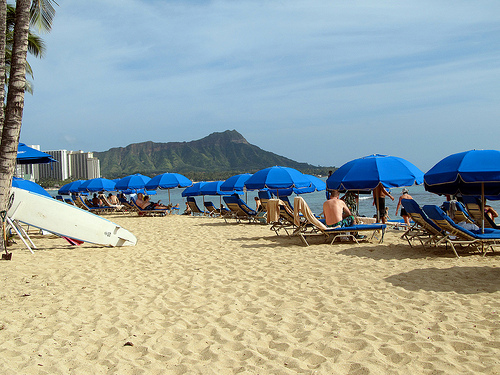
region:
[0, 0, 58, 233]
brown and green palm trees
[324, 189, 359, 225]
man in green swimming trunks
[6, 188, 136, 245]
white and blue surfboard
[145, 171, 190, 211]
large bright blue beach umbrella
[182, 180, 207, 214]
large bright blue beach umbrella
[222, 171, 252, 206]
large bright blue beach umbrella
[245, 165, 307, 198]
large bright blue beach umbrella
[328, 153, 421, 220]
large bright blue beach umbrella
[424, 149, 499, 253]
large bright blue beach umbrella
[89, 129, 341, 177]
green and brown mountain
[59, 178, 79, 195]
the large blue umbrella on the beach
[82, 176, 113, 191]
the large blue umbrella on the beach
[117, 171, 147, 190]
the large blue umbrella on the beach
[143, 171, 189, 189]
the large blue umbrella on the beach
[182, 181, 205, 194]
the large blue umbrella on the beach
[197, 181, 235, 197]
the large blue umbrella on the beach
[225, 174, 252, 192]
the large blue umbrella on the beach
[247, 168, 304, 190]
the large blue umbrella on the beach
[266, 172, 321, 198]
the large blue umbrella on the beach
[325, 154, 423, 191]
the large blue umbrella on the beach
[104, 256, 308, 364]
sand on a beach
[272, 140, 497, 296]
large open blue umbrellas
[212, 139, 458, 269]
blue umbrellas that are large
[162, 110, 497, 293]
blue umbrellas that are open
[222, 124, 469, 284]
blue umbrellas that are outside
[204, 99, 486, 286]
blue umbrellas in the sand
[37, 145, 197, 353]
a surfboard on the sand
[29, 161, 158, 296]
a surfboard on the beach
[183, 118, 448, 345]
beach chairs on the sand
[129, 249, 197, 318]
a beach with sand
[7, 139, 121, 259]
a surfboard on the sand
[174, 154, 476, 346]
umbrellas in the sand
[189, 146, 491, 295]
umbrellas on the beach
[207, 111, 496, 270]
blue umbrellas on the beach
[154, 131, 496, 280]
blue umbrellas on teh sand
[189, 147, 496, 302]
large blue umbrellas open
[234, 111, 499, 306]
large umbrellas in the sand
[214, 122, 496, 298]
a large umbrellas with a beach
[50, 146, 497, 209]
THE UMBRELLAS ARE BLUE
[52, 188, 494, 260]
THE LAWN CHAIRS ARE ON THE BEACH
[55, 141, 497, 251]
THE UMBRELLAS AND CHAIRS ARE TOGETHER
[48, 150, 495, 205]
THE UMBRELLAS ARE ON THE BEACH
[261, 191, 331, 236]
THE TOWELS ARE ON THE CHAIRS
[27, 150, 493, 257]
THE PEOPLE ARE ON THE CHAIRS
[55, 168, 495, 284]
THE PEOPLE ARE VISITING THE BEACH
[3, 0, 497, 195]
THE SKY IS BLUE WITH HAZY CLOUDS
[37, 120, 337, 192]
THE MOUNTAIN IS IN THE DISTANCE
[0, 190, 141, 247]
THE SURF BOARD IS WHITE